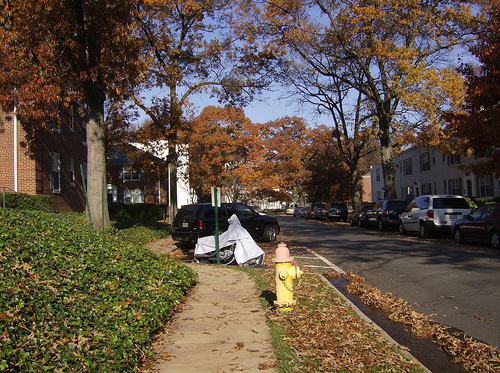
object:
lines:
[300, 263, 333, 270]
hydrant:
[270, 240, 306, 316]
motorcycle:
[193, 210, 264, 266]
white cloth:
[192, 214, 267, 265]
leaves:
[487, 356, 499, 364]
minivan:
[394, 193, 477, 240]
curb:
[304, 187, 499, 229]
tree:
[0, 0, 155, 233]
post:
[211, 187, 222, 266]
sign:
[208, 185, 221, 210]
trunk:
[82, 91, 112, 229]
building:
[0, 68, 88, 214]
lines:
[301, 244, 348, 276]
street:
[272, 208, 499, 371]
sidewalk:
[139, 232, 277, 372]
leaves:
[245, 350, 259, 354]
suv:
[168, 200, 280, 246]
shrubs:
[105, 198, 169, 226]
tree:
[224, 1, 485, 200]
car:
[449, 197, 498, 252]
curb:
[314, 269, 438, 372]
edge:
[27, 140, 40, 193]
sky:
[101, 1, 485, 151]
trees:
[114, 0, 295, 227]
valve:
[278, 272, 289, 281]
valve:
[295, 268, 305, 281]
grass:
[0, 185, 197, 373]